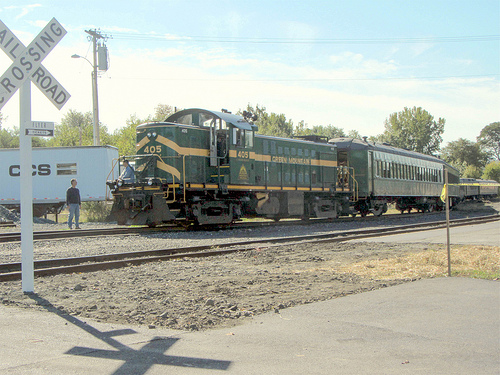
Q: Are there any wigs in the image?
A: No, there are no wigs.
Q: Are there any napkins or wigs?
A: No, there are no wigs or napkins.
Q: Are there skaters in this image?
A: No, there are no skaters.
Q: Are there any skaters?
A: No, there are no skaters.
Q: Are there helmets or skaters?
A: No, there are no skaters or helmets.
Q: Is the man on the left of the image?
A: Yes, the man is on the left of the image.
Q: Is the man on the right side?
A: No, the man is on the left of the image.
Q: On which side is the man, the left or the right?
A: The man is on the left of the image.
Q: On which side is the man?
A: The man is on the left of the image.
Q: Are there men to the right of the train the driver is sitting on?
A: No, the man is to the left of the train.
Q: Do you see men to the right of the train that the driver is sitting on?
A: No, the man is to the left of the train.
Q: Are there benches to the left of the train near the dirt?
A: No, there is a man to the left of the train.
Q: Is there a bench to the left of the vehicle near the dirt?
A: No, there is a man to the left of the train.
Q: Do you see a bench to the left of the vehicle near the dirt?
A: No, there is a man to the left of the train.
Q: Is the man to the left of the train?
A: Yes, the man is to the left of the train.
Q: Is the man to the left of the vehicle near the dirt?
A: Yes, the man is to the left of the train.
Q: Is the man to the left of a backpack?
A: No, the man is to the left of the train.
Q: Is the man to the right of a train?
A: No, the man is to the left of a train.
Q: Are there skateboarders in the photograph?
A: No, there are no skateboarders.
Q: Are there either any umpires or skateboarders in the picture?
A: No, there are no skateboarders or umpires.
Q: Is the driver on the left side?
A: Yes, the driver is on the left of the image.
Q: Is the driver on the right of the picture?
A: No, the driver is on the left of the image.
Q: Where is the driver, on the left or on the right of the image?
A: The driver is on the left of the image.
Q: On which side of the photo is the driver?
A: The driver is on the left of the image.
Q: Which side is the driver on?
A: The driver is on the left of the image.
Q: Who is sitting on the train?
A: The driver is sitting on the train.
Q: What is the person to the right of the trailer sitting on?
A: The driver is sitting on the train.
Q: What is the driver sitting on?
A: The driver is sitting on the train.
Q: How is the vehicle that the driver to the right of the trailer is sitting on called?
A: The vehicle is a train.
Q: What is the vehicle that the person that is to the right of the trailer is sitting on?
A: The vehicle is a train.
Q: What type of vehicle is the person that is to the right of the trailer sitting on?
A: The driver is sitting on the train.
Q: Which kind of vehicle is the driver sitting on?
A: The driver is sitting on the train.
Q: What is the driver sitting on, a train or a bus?
A: The driver is sitting on a train.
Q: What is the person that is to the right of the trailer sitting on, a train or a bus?
A: The driver is sitting on a train.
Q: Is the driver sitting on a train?
A: Yes, the driver is sitting on a train.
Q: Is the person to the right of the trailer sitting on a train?
A: Yes, the driver is sitting on a train.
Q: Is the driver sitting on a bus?
A: No, the driver is sitting on a train.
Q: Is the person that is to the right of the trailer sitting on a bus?
A: No, the driver is sitting on a train.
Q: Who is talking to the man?
A: The driver is talking to the man.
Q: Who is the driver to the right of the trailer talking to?
A: The driver is talking to a man.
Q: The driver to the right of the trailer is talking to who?
A: The driver is talking to a man.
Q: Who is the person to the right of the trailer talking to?
A: The driver is talking to a man.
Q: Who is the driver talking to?
A: The driver is talking to a man.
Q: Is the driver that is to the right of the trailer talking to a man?
A: Yes, the driver is talking to a man.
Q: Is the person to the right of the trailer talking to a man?
A: Yes, the driver is talking to a man.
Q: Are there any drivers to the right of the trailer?
A: Yes, there is a driver to the right of the trailer.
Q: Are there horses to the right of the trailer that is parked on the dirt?
A: No, there is a driver to the right of the trailer.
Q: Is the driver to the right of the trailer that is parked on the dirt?
A: Yes, the driver is to the right of the trailer.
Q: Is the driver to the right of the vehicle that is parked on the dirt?
A: Yes, the driver is to the right of the trailer.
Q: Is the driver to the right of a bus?
A: No, the driver is to the right of the trailer.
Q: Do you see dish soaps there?
A: No, there are no dish soaps.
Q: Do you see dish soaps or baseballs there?
A: No, there are no dish soaps or baseballs.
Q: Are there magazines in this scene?
A: No, there are no magazines.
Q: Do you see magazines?
A: No, there are no magazines.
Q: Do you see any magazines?
A: No, there are no magazines.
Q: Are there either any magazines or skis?
A: No, there are no magazines or skis.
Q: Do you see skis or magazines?
A: No, there are no magazines or skis.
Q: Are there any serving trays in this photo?
A: No, there are no serving trays.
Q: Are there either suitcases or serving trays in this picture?
A: No, there are no serving trays or suitcases.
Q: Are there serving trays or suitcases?
A: No, there are no serving trays or suitcases.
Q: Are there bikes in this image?
A: No, there are no bikes.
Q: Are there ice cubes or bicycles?
A: No, there are no bicycles or ice cubes.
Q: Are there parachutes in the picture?
A: No, there are no parachutes.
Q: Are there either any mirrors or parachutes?
A: No, there are no parachutes or mirrors.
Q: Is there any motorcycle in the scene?
A: No, there are no motorcycles.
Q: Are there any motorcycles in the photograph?
A: No, there are no motorcycles.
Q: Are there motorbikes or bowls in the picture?
A: No, there are no motorbikes or bowls.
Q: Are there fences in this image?
A: No, there are no fences.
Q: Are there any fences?
A: No, there are no fences.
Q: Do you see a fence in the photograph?
A: No, there are no fences.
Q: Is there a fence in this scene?
A: No, there are no fences.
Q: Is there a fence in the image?
A: No, there are no fences.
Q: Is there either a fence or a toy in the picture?
A: No, there are no fences or toys.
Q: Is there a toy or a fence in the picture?
A: No, there are no fences or toys.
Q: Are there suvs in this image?
A: No, there are no suvs.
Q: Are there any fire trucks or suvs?
A: No, there are no suvs or fire trucks.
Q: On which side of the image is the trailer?
A: The trailer is on the left of the image.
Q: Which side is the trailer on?
A: The trailer is on the left of the image.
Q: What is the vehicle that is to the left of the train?
A: The vehicle is a trailer.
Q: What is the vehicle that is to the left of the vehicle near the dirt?
A: The vehicle is a trailer.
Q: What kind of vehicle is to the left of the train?
A: The vehicle is a trailer.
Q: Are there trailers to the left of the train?
A: Yes, there is a trailer to the left of the train.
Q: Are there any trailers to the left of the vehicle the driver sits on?
A: Yes, there is a trailer to the left of the train.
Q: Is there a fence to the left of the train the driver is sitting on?
A: No, there is a trailer to the left of the train.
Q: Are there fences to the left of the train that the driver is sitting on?
A: No, there is a trailer to the left of the train.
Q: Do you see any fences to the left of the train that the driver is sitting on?
A: No, there is a trailer to the left of the train.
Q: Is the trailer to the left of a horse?
A: No, the trailer is to the left of the train.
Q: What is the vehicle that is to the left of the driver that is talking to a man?
A: The vehicle is a trailer.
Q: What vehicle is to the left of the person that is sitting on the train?
A: The vehicle is a trailer.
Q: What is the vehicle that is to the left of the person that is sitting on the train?
A: The vehicle is a trailer.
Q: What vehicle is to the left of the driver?
A: The vehicle is a trailer.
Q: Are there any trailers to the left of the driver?
A: Yes, there is a trailer to the left of the driver.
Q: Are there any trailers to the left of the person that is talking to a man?
A: Yes, there is a trailer to the left of the driver.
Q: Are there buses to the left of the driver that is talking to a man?
A: No, there is a trailer to the left of the driver.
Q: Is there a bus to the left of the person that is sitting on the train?
A: No, there is a trailer to the left of the driver.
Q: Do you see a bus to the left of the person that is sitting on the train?
A: No, there is a trailer to the left of the driver.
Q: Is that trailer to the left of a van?
A: No, the trailer is to the left of the driver.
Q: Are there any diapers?
A: No, there are no diapers.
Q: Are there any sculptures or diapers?
A: No, there are no diapers or sculptures.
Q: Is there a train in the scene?
A: Yes, there is a train.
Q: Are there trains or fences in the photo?
A: Yes, there is a train.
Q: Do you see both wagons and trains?
A: No, there is a train but no wagons.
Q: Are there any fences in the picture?
A: No, there are no fences.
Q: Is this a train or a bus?
A: This is a train.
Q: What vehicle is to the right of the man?
A: The vehicle is a train.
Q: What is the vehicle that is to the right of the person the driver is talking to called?
A: The vehicle is a train.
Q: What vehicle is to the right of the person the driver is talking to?
A: The vehicle is a train.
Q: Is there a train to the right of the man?
A: Yes, there is a train to the right of the man.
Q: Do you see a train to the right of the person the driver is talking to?
A: Yes, there is a train to the right of the man.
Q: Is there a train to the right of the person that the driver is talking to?
A: Yes, there is a train to the right of the man.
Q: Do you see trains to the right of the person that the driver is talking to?
A: Yes, there is a train to the right of the man.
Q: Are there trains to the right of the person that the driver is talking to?
A: Yes, there is a train to the right of the man.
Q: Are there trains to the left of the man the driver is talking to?
A: No, the train is to the right of the man.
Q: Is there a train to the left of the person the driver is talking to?
A: No, the train is to the right of the man.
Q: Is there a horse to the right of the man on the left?
A: No, there is a train to the right of the man.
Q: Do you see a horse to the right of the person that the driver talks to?
A: No, there is a train to the right of the man.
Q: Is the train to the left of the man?
A: No, the train is to the right of the man.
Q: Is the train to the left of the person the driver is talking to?
A: No, the train is to the right of the man.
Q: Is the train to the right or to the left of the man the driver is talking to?
A: The train is to the right of the man.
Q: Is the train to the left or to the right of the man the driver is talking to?
A: The train is to the right of the man.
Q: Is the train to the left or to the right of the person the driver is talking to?
A: The train is to the right of the man.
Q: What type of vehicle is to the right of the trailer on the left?
A: The vehicle is a train.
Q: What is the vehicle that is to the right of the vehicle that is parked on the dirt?
A: The vehicle is a train.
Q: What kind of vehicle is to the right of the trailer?
A: The vehicle is a train.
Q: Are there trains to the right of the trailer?
A: Yes, there is a train to the right of the trailer.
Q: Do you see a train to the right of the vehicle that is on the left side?
A: Yes, there is a train to the right of the trailer.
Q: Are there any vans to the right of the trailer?
A: No, there is a train to the right of the trailer.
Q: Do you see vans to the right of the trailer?
A: No, there is a train to the right of the trailer.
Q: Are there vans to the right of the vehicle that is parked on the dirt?
A: No, there is a train to the right of the trailer.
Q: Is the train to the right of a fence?
A: No, the train is to the right of a trailer.